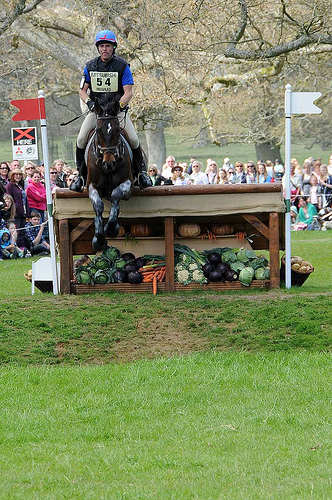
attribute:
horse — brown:
[84, 91, 131, 252]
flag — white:
[289, 92, 316, 114]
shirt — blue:
[106, 68, 137, 83]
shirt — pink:
[25, 187, 46, 216]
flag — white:
[248, 69, 328, 177]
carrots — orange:
[139, 260, 163, 287]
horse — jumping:
[79, 92, 134, 245]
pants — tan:
[112, 114, 140, 150]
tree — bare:
[107, 39, 201, 180]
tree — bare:
[0, 0, 86, 144]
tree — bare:
[143, 25, 281, 146]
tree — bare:
[222, 0, 330, 169]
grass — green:
[0, 229, 330, 499]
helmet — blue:
[90, 27, 118, 49]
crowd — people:
[147, 152, 329, 231]